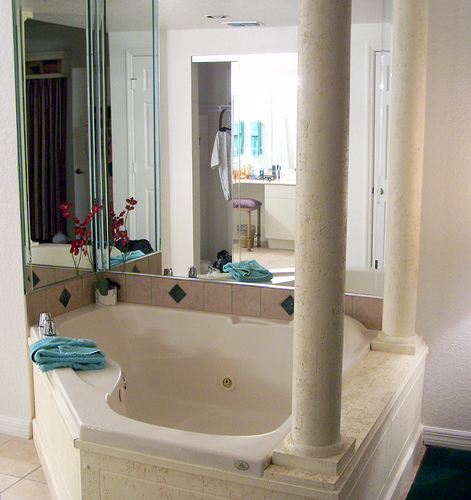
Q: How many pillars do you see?
A: Two.